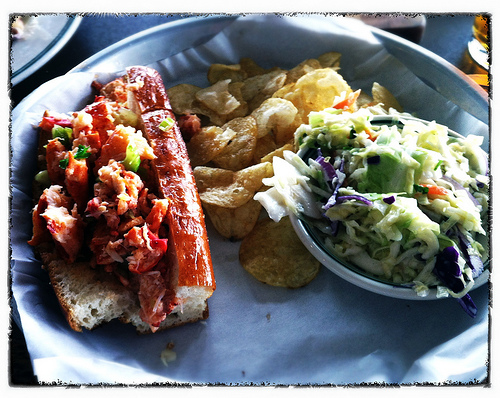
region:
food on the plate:
[38, 66, 484, 361]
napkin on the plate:
[225, 301, 421, 378]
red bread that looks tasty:
[4, 117, 263, 306]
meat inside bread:
[63, 138, 153, 275]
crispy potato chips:
[199, 75, 267, 154]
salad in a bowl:
[308, 145, 472, 260]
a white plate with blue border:
[15, 22, 66, 56]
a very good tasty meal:
[28, 25, 473, 364]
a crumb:
[231, 296, 347, 366]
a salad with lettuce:
[308, 121, 499, 270]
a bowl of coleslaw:
[285, 99, 497, 296]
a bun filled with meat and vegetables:
[32, 59, 207, 319]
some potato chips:
[170, 73, 355, 110]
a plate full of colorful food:
[8, 19, 482, 373]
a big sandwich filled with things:
[22, 65, 214, 315]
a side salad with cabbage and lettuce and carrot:
[288, 105, 493, 304]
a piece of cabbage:
[436, 241, 478, 313]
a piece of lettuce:
[382, 185, 442, 256]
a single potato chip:
[233, 215, 328, 290]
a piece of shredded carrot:
[426, 184, 446, 199]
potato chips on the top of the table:
[213, 68, 312, 282]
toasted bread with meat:
[55, 86, 260, 307]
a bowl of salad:
[281, 87, 471, 296]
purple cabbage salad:
[282, 145, 391, 215]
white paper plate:
[169, 290, 402, 367]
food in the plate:
[64, 42, 488, 322]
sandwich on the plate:
[34, 67, 205, 338]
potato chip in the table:
[180, 60, 312, 312]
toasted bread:
[96, 67, 224, 280]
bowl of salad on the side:
[277, 116, 497, 287]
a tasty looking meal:
[10, 16, 494, 388]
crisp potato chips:
[187, 65, 278, 181]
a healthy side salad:
[257, 100, 489, 312]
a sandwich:
[35, 60, 220, 346]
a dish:
[120, 22, 180, 58]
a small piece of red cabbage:
[321, 160, 367, 210]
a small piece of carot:
[425, 180, 445, 196]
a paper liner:
[230, 310, 380, 370]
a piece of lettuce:
[260, 156, 315, 221]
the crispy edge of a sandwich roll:
[161, 150, 222, 293]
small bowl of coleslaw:
[313, 116, 495, 278]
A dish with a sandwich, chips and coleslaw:
[32, 28, 492, 377]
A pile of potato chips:
[196, 56, 291, 145]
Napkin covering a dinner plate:
[134, 1, 306, 62]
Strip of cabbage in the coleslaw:
[313, 153, 343, 183]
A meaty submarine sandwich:
[40, 68, 197, 333]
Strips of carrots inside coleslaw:
[418, 179, 450, 195]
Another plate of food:
[3, 12, 65, 65]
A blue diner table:
[83, 7, 138, 42]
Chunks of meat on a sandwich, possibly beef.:
[75, 178, 165, 309]